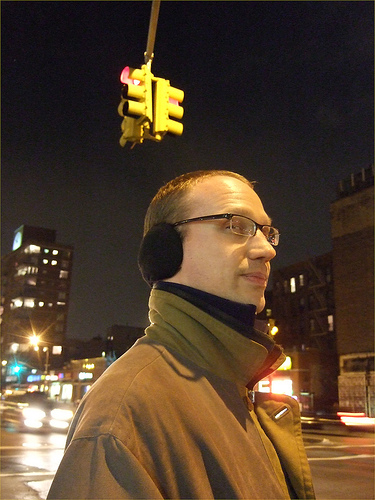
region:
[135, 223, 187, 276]
The black ear muff on the man's ear.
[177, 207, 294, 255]
The eyeglasses the man is wearing.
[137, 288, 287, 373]
The beige collar of the man's jacket.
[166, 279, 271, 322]
The black collar of the man's jacket.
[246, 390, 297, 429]
The flap of the man's beige jacket.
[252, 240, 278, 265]
The nose of the man.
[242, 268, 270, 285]
The lips of the man.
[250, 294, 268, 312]
The chin of the man.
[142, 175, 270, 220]
The forehead of the man.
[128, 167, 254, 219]
The short hair of the man.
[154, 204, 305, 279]
the man is wearing eyeglass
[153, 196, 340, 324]
the man is wearing eyeglass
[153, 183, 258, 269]
the man is wearing eyeglass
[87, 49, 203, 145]
the traffic lights above the man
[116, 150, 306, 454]
the man wearing earmuffs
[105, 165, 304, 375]
the man wearing glasses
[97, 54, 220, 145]
the traffic lights are hanging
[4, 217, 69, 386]
the tallest building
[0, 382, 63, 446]
the car in the street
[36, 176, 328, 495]
the man wearing a jacket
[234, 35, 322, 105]
the sky is black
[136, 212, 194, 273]
the earmuffs are black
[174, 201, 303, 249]
the glasses are black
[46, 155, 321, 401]
Man is wearing earmuffs.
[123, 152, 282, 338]
The earmuffs are black.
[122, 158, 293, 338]
Man is wearing glasses.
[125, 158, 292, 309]
The man has hair.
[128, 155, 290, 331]
Man's hair is short.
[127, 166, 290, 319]
Man hair is brown.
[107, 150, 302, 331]
Man's hair is neat.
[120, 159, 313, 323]
Man's hair is groomed.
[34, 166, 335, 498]
Man is wearing jacket.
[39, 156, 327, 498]
The jacket is tan.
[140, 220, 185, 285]
black wrap-around ear muff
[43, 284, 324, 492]
brown jacket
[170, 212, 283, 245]
black thin frame glasses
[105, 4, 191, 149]
traffic light on a red light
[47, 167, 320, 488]
man in glasses and ear muffs outside at night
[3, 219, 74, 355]
large tall building at night with some windows illuminated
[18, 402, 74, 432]
car headlights turned on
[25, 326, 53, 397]
illuminated street lamp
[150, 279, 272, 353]
black turtleneck shirt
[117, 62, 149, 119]
red traffic light